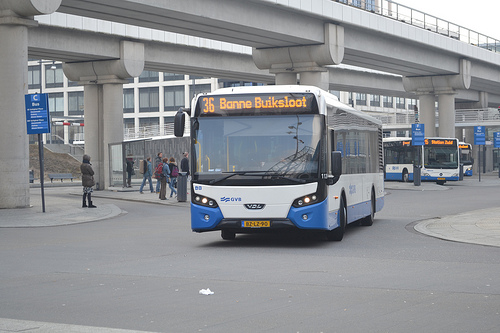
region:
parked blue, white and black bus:
[189, 88, 382, 242]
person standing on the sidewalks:
[77, 153, 97, 208]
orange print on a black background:
[194, 94, 316, 116]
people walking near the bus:
[124, 148, 191, 203]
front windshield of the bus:
[192, 117, 331, 183]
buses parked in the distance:
[383, 137, 472, 183]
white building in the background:
[7, 56, 419, 136]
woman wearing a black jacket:
[78, 163, 93, 180]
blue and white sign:
[24, 92, 51, 134]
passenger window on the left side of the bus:
[326, 103, 382, 174]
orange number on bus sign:
[201, 95, 209, 112]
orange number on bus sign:
[206, 95, 215, 112]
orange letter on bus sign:
[218, 95, 226, 110]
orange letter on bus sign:
[225, 99, 233, 111]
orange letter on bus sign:
[230, 98, 239, 108]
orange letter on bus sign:
[236, 99, 246, 110]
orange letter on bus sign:
[242, 99, 252, 111]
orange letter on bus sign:
[254, 95, 262, 108]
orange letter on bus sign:
[259, 99, 268, 108]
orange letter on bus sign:
[295, 96, 303, 109]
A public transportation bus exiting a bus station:
[167, 80, 392, 255]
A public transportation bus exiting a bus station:
[166, 83, 391, 244]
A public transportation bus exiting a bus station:
[165, 82, 387, 247]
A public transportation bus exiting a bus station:
[170, 82, 386, 242]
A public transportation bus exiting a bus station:
[170, 82, 385, 247]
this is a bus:
[146, 68, 398, 250]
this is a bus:
[379, 135, 463, 197]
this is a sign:
[11, 79, 85, 166]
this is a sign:
[407, 107, 441, 154]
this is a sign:
[465, 115, 491, 149]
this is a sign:
[494, 133, 499, 160]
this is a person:
[64, 138, 109, 214]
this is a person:
[139, 144, 164, 197]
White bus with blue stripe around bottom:
[173, 84, 386, 241]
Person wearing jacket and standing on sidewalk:
[79, 153, 98, 209]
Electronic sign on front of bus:
[196, 93, 308, 115]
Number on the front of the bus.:
[201, 96, 215, 111]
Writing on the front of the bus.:
[219, 97, 308, 107]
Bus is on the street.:
[174, 85, 387, 241]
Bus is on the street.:
[382, 134, 461, 182]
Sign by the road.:
[23, 90, 51, 212]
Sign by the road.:
[410, 121, 427, 186]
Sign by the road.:
[474, 123, 487, 181]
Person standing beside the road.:
[81, 154, 95, 206]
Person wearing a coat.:
[79, 154, 94, 186]